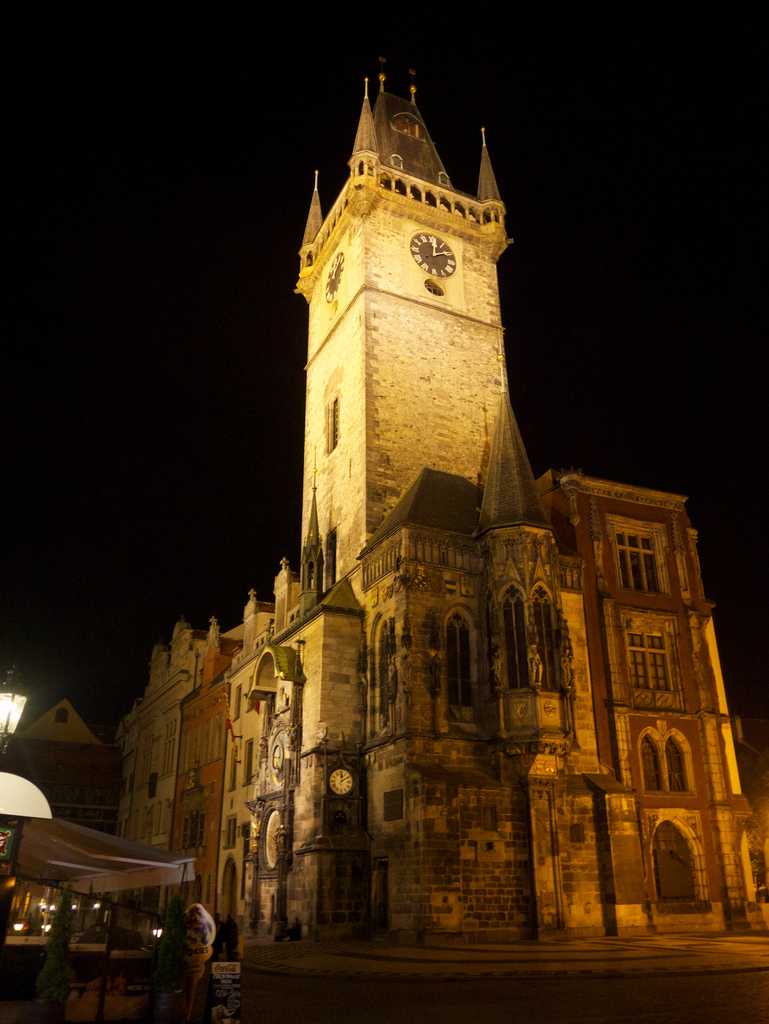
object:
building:
[119, 75, 728, 932]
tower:
[279, 69, 517, 573]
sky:
[0, 3, 291, 577]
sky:
[502, 5, 746, 469]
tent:
[0, 775, 196, 899]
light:
[0, 769, 52, 822]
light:
[10, 921, 26, 933]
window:
[636, 727, 694, 799]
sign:
[208, 956, 248, 1023]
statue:
[525, 607, 545, 686]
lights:
[39, 921, 51, 936]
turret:
[344, 65, 380, 184]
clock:
[407, 230, 459, 283]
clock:
[325, 764, 357, 797]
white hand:
[431, 237, 437, 256]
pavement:
[225, 932, 760, 973]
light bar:
[3, 684, 28, 744]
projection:
[376, 67, 389, 95]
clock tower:
[296, 48, 513, 501]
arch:
[647, 821, 705, 905]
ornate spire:
[471, 350, 551, 534]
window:
[328, 399, 343, 449]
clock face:
[325, 252, 346, 302]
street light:
[0, 684, 29, 747]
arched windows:
[631, 724, 694, 800]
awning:
[24, 823, 193, 896]